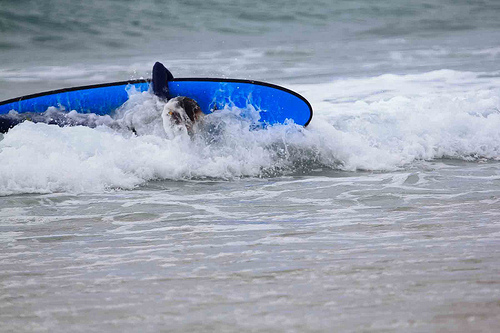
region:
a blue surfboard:
[0, 58, 316, 200]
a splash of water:
[4, 97, 309, 207]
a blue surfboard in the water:
[2, 60, 315, 216]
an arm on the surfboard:
[148, 59, 175, 99]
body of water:
[2, 3, 499, 42]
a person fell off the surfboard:
[1, 60, 319, 175]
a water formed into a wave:
[316, 65, 497, 181]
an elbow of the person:
[151, 58, 171, 84]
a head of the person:
[168, 94, 203, 124]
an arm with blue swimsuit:
[148, 60, 174, 99]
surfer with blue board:
[21, 52, 342, 155]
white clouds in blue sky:
[392, 30, 443, 74]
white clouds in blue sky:
[274, 37, 327, 69]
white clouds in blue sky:
[62, 14, 124, 71]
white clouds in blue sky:
[223, 221, 290, 272]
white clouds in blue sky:
[364, 168, 406, 209]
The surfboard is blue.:
[2, 61, 334, 161]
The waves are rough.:
[7, 113, 308, 190]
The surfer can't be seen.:
[82, 90, 245, 152]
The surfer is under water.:
[99, 75, 234, 143]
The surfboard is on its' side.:
[1, 62, 332, 174]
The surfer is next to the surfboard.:
[88, 60, 260, 164]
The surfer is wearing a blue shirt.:
[141, 53, 190, 113]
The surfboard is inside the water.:
[14, 61, 328, 184]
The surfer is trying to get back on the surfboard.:
[3, 62, 315, 172]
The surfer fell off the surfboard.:
[7, 61, 334, 199]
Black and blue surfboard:
[1, 68, 322, 175]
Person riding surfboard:
[0, 60, 221, 161]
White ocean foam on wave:
[4, 61, 499, 184]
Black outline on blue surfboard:
[4, 72, 335, 127]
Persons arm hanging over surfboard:
[139, 45, 182, 109]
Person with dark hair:
[155, 75, 215, 136]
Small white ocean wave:
[1, 78, 493, 208]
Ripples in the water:
[4, 0, 496, 66]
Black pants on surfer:
[0, 101, 158, 132]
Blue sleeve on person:
[134, 60, 186, 110]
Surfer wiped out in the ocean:
[15, 34, 350, 162]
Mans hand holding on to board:
[112, 42, 252, 151]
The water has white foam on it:
[304, 56, 499, 197]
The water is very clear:
[207, 213, 337, 328]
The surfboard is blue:
[37, 82, 360, 164]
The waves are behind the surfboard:
[22, 6, 359, 52]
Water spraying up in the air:
[182, 91, 324, 193]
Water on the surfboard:
[37, 86, 97, 113]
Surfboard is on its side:
[21, 38, 394, 105]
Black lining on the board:
[219, 65, 292, 117]